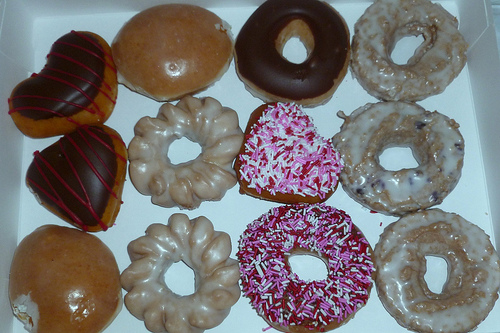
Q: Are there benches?
A: No, there are no benches.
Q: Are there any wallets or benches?
A: No, there are no benches or wallets.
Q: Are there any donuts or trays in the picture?
A: Yes, there is a donut.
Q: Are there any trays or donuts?
A: Yes, there is a donut.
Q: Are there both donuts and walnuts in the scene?
A: No, there is a donut but no walnuts.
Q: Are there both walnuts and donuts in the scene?
A: No, there is a donut but no walnuts.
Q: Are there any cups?
A: No, there are no cups.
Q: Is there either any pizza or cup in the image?
A: No, there are no cups or pizzas.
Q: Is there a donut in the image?
A: Yes, there is a donut.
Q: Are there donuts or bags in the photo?
A: Yes, there is a donut.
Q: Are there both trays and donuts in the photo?
A: No, there is a donut but no trays.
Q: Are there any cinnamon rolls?
A: No, there are no cinnamon rolls.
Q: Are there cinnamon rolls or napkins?
A: No, there are no cinnamon rolls or napkins.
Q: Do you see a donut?
A: Yes, there is a donut.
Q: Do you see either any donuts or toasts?
A: Yes, there is a donut.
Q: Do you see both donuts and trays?
A: No, there is a donut but no trays.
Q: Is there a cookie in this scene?
A: No, there are no cookies.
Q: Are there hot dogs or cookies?
A: No, there are no cookies or hot dogs.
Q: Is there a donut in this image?
A: Yes, there is a donut.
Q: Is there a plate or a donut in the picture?
A: Yes, there is a donut.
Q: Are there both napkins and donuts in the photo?
A: No, there is a donut but no napkins.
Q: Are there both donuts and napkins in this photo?
A: No, there is a donut but no napkins.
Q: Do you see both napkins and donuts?
A: No, there is a donut but no napkins.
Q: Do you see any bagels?
A: No, there are no bagels.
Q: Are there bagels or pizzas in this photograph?
A: No, there are no bagels or pizzas.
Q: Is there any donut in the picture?
A: Yes, there is a donut.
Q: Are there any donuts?
A: Yes, there is a donut.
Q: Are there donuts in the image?
A: Yes, there is a donut.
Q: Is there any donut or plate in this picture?
A: Yes, there is a donut.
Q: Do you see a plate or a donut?
A: Yes, there is a donut.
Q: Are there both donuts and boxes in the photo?
A: Yes, there are both a donut and a box.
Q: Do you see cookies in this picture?
A: No, there are no cookies.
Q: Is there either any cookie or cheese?
A: No, there are no cookies or cheese.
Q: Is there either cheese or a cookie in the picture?
A: No, there are no cookies or cheese.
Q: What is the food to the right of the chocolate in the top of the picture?
A: The food is a donut.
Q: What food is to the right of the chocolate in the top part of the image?
A: The food is a donut.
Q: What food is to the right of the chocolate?
A: The food is a donut.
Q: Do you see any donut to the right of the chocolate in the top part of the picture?
A: Yes, there is a donut to the right of the chocolate.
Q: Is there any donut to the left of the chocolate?
A: No, the donut is to the right of the chocolate.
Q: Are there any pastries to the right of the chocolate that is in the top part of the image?
A: No, there is a donut to the right of the chocolate.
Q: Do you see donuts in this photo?
A: Yes, there is a donut.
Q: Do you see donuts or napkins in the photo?
A: Yes, there is a donut.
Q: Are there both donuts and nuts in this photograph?
A: No, there is a donut but no nuts.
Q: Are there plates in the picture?
A: No, there are no plates.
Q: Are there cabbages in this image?
A: No, there are no cabbages.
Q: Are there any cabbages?
A: No, there are no cabbages.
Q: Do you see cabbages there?
A: No, there are no cabbages.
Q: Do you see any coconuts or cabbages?
A: No, there are no cabbages or coconuts.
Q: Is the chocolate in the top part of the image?
A: Yes, the chocolate is in the top of the image.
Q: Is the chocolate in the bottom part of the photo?
A: No, the chocolate is in the top of the image.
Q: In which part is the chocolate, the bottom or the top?
A: The chocolate is in the top of the image.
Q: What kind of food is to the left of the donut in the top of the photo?
A: The food is chocolate.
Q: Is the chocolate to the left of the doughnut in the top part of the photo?
A: Yes, the chocolate is to the left of the doughnut.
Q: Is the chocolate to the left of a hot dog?
A: No, the chocolate is to the left of the doughnut.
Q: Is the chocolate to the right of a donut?
A: No, the chocolate is to the left of a donut.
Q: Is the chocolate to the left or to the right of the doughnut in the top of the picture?
A: The chocolate is to the left of the donut.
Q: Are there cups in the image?
A: No, there are no cups.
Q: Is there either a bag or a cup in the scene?
A: No, there are no cups or bags.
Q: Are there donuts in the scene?
A: Yes, there is a donut.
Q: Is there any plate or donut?
A: Yes, there is a donut.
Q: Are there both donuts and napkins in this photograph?
A: No, there is a donut but no napkins.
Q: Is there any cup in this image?
A: No, there are no cups.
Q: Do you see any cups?
A: No, there are no cups.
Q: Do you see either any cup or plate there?
A: No, there are no cups or plates.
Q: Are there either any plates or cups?
A: No, there are no cups or plates.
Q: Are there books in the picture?
A: No, there are no books.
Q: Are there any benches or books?
A: No, there are no books or benches.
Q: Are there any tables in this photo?
A: Yes, there is a table.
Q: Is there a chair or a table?
A: Yes, there is a table.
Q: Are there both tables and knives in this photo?
A: No, there is a table but no knives.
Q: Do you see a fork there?
A: No, there are no forks.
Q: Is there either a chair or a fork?
A: No, there are no forks or chairs.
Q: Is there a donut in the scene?
A: Yes, there is a donut.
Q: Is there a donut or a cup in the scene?
A: Yes, there is a donut.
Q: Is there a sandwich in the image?
A: No, there are no sandwiches.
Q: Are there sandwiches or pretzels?
A: No, there are no sandwiches or pretzels.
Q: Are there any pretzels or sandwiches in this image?
A: No, there are no sandwiches or pretzels.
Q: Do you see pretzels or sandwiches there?
A: No, there are no sandwiches or pretzels.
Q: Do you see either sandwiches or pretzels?
A: No, there are no sandwiches or pretzels.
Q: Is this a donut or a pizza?
A: This is a donut.